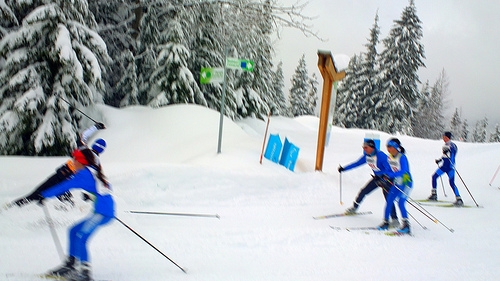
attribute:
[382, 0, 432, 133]
tree — tall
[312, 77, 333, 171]
sign post — brown, yellow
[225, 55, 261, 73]
sign — green, green arrow, blue, white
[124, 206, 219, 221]
pole — black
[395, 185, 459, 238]
pole — silver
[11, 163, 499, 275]
slope — white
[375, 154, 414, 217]
ski suit — blue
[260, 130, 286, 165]
flag — blue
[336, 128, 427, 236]
skiers — side by side, skiing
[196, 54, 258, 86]
signs — green, white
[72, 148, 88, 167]
head band — red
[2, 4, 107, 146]
pine tree — covered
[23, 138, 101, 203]
skier — wiping out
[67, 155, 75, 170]
vest — yellow, orange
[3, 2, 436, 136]
trees — heavy, covered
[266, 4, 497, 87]
sky — gray